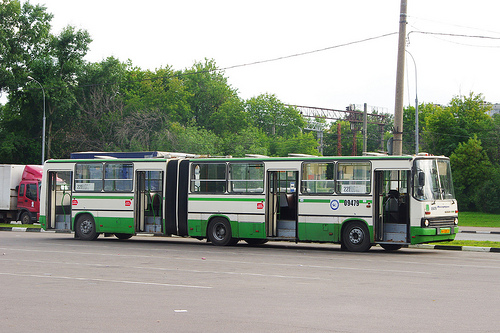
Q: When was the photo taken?
A: During the day.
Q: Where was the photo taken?
A: In a parking lot.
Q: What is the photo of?
A: A bus.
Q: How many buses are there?
A: One.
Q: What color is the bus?
A: Green and white.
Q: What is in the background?
A: Trees.